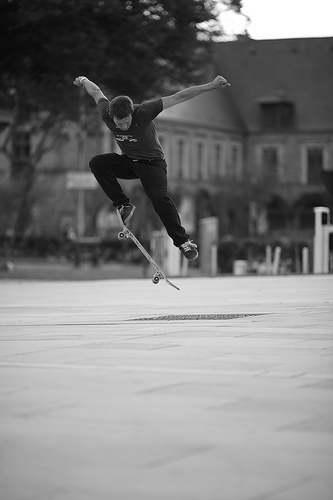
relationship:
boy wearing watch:
[71, 72, 231, 261] [78, 75, 91, 84]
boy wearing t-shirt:
[71, 75, 231, 263] [94, 95, 167, 160]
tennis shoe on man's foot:
[176, 242, 201, 261] [156, 226, 208, 268]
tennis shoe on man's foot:
[117, 198, 137, 226] [112, 196, 131, 220]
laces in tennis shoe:
[178, 242, 194, 253] [177, 240, 200, 263]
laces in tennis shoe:
[115, 202, 126, 214] [119, 199, 136, 227]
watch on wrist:
[78, 75, 96, 84] [76, 74, 87, 90]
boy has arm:
[71, 75, 231, 263] [71, 70, 232, 111]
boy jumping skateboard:
[71, 75, 231, 263] [116, 212, 177, 290]